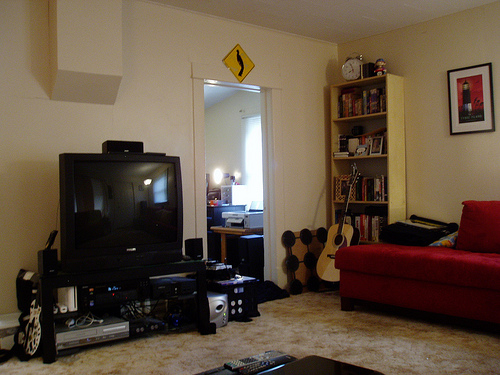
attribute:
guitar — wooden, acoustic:
[310, 161, 370, 291]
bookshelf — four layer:
[321, 72, 411, 272]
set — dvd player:
[53, 320, 136, 350]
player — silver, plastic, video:
[51, 316, 133, 347]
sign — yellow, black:
[220, 36, 257, 85]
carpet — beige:
[2, 288, 484, 373]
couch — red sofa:
[336, 201, 499, 331]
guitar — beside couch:
[315, 168, 360, 284]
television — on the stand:
[56, 154, 183, 268]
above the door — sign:
[203, 44, 275, 259]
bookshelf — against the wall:
[327, 76, 408, 243]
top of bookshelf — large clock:
[327, 54, 408, 90]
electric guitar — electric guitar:
[1, 228, 60, 367]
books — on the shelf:
[334, 87, 384, 216]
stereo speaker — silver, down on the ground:
[208, 291, 231, 327]